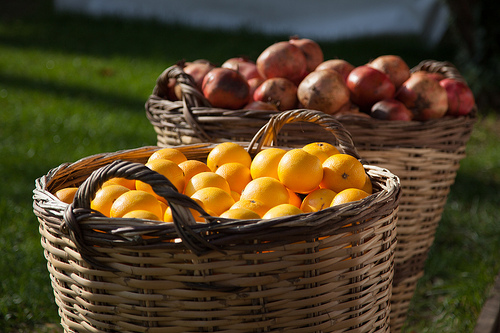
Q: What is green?
A: The grass.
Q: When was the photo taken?
A: Day time.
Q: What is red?
A: The pomegranates.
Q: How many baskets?
A: Two.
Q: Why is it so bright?
A: Sunny.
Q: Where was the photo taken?
A: A fruit orchard.